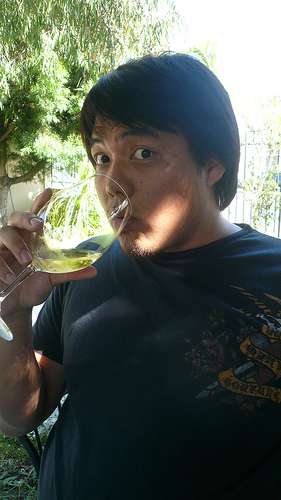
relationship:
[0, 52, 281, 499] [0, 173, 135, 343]
man drinking wine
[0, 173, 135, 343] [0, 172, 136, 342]
wine in glass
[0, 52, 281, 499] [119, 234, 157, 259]
man has beard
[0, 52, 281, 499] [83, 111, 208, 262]
man has face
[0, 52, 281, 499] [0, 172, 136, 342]
man holding glass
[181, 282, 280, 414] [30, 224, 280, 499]
design on shirt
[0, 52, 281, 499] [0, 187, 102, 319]
man has hand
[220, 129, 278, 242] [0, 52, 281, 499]
fence behind man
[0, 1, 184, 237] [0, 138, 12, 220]
tree has trunk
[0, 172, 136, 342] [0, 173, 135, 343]
glass for wine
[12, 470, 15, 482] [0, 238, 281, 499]
grass on ground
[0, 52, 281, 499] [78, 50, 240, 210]
man with hair